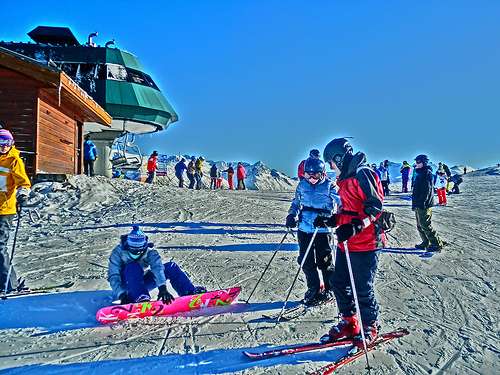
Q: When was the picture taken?
A: During the daylight.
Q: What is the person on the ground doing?
A: Putting on the board.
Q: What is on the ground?
A: The snow.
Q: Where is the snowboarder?
A: On the ground.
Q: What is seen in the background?
A: The ski lodge.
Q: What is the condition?
A: The sky is clear and blue.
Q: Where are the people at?
A: The ski hill.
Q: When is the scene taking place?
A: During the daylight hours on the hill.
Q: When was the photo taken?
A: During the daytime.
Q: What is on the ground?
A: Snow.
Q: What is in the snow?
A: Tracks.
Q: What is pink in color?
A: The board.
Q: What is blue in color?
A: Sky.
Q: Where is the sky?
A: Above the land.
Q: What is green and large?
A: A building.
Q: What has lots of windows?
A: Green building.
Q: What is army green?
A: Pants.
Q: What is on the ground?
A: Snow.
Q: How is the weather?
A: Cold.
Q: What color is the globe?
A: Aqua.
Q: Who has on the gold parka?
A: A man.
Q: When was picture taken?
A: Daytime.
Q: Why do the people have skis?
A: To ski.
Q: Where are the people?
A: Ski park.